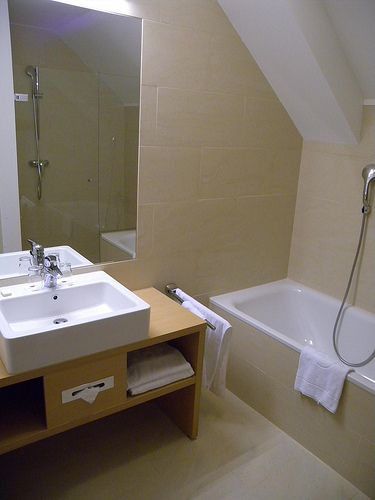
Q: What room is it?
A: It is a bathroom.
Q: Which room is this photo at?
A: It is at the bathroom.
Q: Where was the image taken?
A: It was taken at the bathroom.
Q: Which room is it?
A: It is a bathroom.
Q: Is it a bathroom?
A: Yes, it is a bathroom.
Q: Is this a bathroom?
A: Yes, it is a bathroom.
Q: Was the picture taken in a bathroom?
A: Yes, it was taken in a bathroom.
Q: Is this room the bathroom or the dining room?
A: It is the bathroom.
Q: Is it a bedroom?
A: No, it is a bathroom.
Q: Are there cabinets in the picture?
A: Yes, there is a cabinet.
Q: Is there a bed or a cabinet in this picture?
A: Yes, there is a cabinet.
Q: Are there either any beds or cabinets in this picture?
A: Yes, there is a cabinet.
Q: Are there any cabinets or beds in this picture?
A: Yes, there is a cabinet.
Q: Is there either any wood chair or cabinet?
A: Yes, there is a wood cabinet.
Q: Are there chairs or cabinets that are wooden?
A: Yes, the cabinet is wooden.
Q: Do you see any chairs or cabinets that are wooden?
A: Yes, the cabinet is wooden.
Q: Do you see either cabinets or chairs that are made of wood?
A: Yes, the cabinet is made of wood.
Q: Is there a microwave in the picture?
A: No, there are no microwaves.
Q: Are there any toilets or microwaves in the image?
A: No, there are no microwaves or toilets.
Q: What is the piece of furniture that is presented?
A: The piece of furniture is a cabinet.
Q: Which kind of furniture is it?
A: The piece of furniture is a cabinet.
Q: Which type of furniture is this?
A: This is a cabinet.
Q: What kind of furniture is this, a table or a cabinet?
A: This is a cabinet.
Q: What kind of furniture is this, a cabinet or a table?
A: This is a cabinet.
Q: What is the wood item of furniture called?
A: The piece of furniture is a cabinet.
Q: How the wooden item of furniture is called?
A: The piece of furniture is a cabinet.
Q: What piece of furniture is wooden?
A: The piece of furniture is a cabinet.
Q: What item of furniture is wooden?
A: The piece of furniture is a cabinet.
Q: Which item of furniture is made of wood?
A: The piece of furniture is a cabinet.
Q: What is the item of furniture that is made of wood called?
A: The piece of furniture is a cabinet.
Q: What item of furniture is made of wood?
A: The piece of furniture is a cabinet.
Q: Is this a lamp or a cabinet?
A: This is a cabinet.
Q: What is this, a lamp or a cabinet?
A: This is a cabinet.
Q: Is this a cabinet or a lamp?
A: This is a cabinet.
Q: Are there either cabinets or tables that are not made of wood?
A: No, there is a cabinet but it is made of wood.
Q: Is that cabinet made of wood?
A: Yes, the cabinet is made of wood.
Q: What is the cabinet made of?
A: The cabinet is made of wood.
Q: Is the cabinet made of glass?
A: No, the cabinet is made of wood.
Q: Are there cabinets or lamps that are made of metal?
A: No, there is a cabinet but it is made of wood.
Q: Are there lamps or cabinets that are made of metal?
A: No, there is a cabinet but it is made of wood.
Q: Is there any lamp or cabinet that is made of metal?
A: No, there is a cabinet but it is made of wood.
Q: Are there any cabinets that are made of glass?
A: No, there is a cabinet but it is made of wood.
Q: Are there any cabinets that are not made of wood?
A: No, there is a cabinet but it is made of wood.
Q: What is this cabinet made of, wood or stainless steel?
A: The cabinet is made of wood.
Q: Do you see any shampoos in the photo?
A: No, there are no shampoos.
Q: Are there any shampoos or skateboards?
A: No, there are no shampoos or skateboards.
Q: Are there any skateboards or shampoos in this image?
A: No, there are no shampoos or skateboards.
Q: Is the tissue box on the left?
A: Yes, the tissue box is on the left of the image.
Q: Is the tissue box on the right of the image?
A: No, the tissue box is on the left of the image.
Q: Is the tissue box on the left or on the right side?
A: The tissue box is on the left of the image.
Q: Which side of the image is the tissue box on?
A: The tissue box is on the left of the image.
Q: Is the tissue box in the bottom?
A: Yes, the tissue box is in the bottom of the image.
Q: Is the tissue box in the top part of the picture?
A: No, the tissue box is in the bottom of the image.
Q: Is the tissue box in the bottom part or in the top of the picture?
A: The tissue box is in the bottom of the image.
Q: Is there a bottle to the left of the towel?
A: No, there is a tissue box to the left of the towel.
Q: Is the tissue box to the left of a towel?
A: Yes, the tissue box is to the left of a towel.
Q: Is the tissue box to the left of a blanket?
A: No, the tissue box is to the left of a towel.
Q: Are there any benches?
A: No, there are no benches.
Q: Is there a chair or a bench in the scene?
A: No, there are no benches or chairs.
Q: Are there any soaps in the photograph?
A: No, there are no soaps.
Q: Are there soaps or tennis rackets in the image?
A: No, there are no soaps or tennis rackets.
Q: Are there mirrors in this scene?
A: Yes, there is a mirror.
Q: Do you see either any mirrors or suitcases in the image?
A: Yes, there is a mirror.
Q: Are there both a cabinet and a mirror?
A: Yes, there are both a mirror and a cabinet.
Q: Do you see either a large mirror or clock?
A: Yes, there is a large mirror.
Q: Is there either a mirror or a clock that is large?
A: Yes, the mirror is large.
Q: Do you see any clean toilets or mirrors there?
A: Yes, there is a clean mirror.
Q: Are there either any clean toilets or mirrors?
A: Yes, there is a clean mirror.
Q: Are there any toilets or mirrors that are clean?
A: Yes, the mirror is clean.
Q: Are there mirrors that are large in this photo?
A: Yes, there is a large mirror.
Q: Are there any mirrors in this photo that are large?
A: Yes, there is a mirror that is large.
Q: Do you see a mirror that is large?
A: Yes, there is a mirror that is large.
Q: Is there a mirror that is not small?
A: Yes, there is a large mirror.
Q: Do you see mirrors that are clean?
A: Yes, there is a clean mirror.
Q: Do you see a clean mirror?
A: Yes, there is a clean mirror.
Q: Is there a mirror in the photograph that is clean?
A: Yes, there is a mirror that is clean.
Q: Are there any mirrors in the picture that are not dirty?
A: Yes, there is a clean mirror.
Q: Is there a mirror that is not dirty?
A: Yes, there is a clean mirror.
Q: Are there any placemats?
A: No, there are no placemats.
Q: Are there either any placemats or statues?
A: No, there are no placemats or statues.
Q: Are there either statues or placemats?
A: No, there are no placemats or statues.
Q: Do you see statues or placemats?
A: No, there are no placemats or statues.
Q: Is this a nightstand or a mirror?
A: This is a mirror.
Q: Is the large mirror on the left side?
A: Yes, the mirror is on the left of the image.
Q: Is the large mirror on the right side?
A: No, the mirror is on the left of the image.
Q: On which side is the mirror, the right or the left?
A: The mirror is on the left of the image.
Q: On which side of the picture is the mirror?
A: The mirror is on the left of the image.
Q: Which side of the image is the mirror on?
A: The mirror is on the left of the image.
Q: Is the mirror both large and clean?
A: Yes, the mirror is large and clean.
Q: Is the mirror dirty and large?
A: No, the mirror is large but clean.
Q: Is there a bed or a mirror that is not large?
A: No, there is a mirror but it is large.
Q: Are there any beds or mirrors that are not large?
A: No, there is a mirror but it is large.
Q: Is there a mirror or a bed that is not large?
A: No, there is a mirror but it is large.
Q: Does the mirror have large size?
A: Yes, the mirror is large.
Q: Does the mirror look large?
A: Yes, the mirror is large.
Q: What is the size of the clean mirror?
A: The mirror is large.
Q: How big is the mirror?
A: The mirror is large.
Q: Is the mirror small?
A: No, the mirror is large.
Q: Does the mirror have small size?
A: No, the mirror is large.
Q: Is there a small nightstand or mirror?
A: No, there is a mirror but it is large.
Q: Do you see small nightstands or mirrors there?
A: No, there is a mirror but it is large.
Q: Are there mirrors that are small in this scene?
A: No, there is a mirror but it is large.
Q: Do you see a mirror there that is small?
A: No, there is a mirror but it is large.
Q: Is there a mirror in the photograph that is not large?
A: No, there is a mirror but it is large.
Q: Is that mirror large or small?
A: The mirror is large.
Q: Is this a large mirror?
A: Yes, this is a large mirror.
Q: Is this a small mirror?
A: No, this is a large mirror.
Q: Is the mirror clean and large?
A: Yes, the mirror is clean and large.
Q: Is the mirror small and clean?
A: No, the mirror is clean but large.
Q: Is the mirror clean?
A: Yes, the mirror is clean.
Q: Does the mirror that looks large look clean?
A: Yes, the mirror is clean.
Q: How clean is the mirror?
A: The mirror is clean.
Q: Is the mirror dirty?
A: No, the mirror is clean.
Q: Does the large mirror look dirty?
A: No, the mirror is clean.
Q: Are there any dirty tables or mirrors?
A: No, there is a mirror but it is clean.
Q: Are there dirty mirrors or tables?
A: No, there is a mirror but it is clean.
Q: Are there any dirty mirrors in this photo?
A: No, there is a mirror but it is clean.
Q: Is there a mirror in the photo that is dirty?
A: No, there is a mirror but it is clean.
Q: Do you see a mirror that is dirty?
A: No, there is a mirror but it is clean.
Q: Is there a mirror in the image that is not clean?
A: No, there is a mirror but it is clean.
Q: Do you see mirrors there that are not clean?
A: No, there is a mirror but it is clean.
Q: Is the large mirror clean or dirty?
A: The mirror is clean.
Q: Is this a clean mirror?
A: Yes, this is a clean mirror.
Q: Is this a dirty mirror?
A: No, this is a clean mirror.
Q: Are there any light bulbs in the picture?
A: No, there are no light bulbs.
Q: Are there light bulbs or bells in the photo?
A: No, there are no light bulbs or bells.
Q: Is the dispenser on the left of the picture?
A: Yes, the dispenser is on the left of the image.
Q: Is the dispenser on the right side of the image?
A: No, the dispenser is on the left of the image.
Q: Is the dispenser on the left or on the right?
A: The dispenser is on the left of the image.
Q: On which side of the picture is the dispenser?
A: The dispenser is on the left of the image.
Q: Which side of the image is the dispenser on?
A: The dispenser is on the left of the image.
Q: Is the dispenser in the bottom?
A: Yes, the dispenser is in the bottom of the image.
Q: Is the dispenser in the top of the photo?
A: No, the dispenser is in the bottom of the image.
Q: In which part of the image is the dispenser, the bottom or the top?
A: The dispenser is in the bottom of the image.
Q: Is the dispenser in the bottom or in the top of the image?
A: The dispenser is in the bottom of the image.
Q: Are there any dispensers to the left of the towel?
A: Yes, there is a dispenser to the left of the towel.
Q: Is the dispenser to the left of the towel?
A: Yes, the dispenser is to the left of the towel.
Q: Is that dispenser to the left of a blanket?
A: No, the dispenser is to the left of the towel.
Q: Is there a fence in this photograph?
A: No, there are no fences.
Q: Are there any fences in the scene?
A: No, there are no fences.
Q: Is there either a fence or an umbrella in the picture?
A: No, there are no fences or umbrellas.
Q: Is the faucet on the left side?
A: Yes, the faucet is on the left of the image.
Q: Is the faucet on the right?
A: No, the faucet is on the left of the image.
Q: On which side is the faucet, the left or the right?
A: The faucet is on the left of the image.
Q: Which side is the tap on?
A: The tap is on the left of the image.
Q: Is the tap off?
A: Yes, the tap is off.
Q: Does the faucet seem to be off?
A: Yes, the faucet is off.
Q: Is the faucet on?
A: No, the faucet is off.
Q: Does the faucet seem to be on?
A: No, the faucet is off.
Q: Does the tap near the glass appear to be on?
A: No, the tap is off.